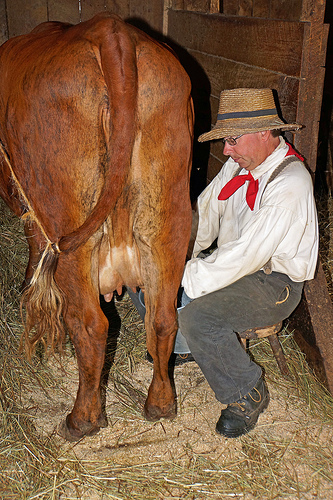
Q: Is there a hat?
A: Yes, there is a hat.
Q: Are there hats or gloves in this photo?
A: Yes, there is a hat.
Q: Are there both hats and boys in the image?
A: No, there is a hat but no boys.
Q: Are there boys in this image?
A: No, there are no boys.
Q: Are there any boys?
A: No, there are no boys.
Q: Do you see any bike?
A: No, there are no bikes.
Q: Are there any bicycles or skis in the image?
A: No, there are no bicycles or skis.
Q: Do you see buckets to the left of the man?
A: Yes, there is a bucket to the left of the man.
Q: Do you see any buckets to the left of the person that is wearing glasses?
A: Yes, there is a bucket to the left of the man.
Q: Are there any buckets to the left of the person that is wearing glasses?
A: Yes, there is a bucket to the left of the man.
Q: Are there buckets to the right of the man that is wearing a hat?
A: No, the bucket is to the left of the man.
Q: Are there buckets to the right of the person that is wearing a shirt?
A: No, the bucket is to the left of the man.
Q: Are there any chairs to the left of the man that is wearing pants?
A: No, there is a bucket to the left of the man.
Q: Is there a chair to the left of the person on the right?
A: No, there is a bucket to the left of the man.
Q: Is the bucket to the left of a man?
A: Yes, the bucket is to the left of a man.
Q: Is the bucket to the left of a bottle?
A: No, the bucket is to the left of a man.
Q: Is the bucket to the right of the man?
A: No, the bucket is to the left of the man.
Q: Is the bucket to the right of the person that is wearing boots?
A: No, the bucket is to the left of the man.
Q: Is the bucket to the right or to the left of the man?
A: The bucket is to the left of the man.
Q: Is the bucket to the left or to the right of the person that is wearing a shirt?
A: The bucket is to the left of the man.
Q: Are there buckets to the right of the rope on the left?
A: Yes, there is a bucket to the right of the rope.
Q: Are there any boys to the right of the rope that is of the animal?
A: No, there is a bucket to the right of the rope.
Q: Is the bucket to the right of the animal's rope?
A: Yes, the bucket is to the right of the rope.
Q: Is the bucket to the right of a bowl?
A: No, the bucket is to the right of the rope.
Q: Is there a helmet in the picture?
A: No, there are no helmets.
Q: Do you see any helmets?
A: No, there are no helmets.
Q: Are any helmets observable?
A: No, there are no helmets.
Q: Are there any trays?
A: No, there are no trays.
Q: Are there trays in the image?
A: No, there are no trays.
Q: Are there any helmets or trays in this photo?
A: No, there are no trays or helmets.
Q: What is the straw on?
A: The straw is on the hay.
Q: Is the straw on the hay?
A: Yes, the straw is on the hay.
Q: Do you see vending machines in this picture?
A: No, there are no vending machines.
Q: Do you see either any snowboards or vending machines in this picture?
A: No, there are no vending machines or snowboards.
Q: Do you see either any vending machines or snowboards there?
A: No, there are no vending machines or snowboards.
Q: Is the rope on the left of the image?
A: Yes, the rope is on the left of the image.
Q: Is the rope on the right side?
A: No, the rope is on the left of the image.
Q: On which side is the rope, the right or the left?
A: The rope is on the left of the image.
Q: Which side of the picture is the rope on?
A: The rope is on the left of the image.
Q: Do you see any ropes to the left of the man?
A: Yes, there is a rope to the left of the man.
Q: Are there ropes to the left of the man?
A: Yes, there is a rope to the left of the man.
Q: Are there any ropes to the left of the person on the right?
A: Yes, there is a rope to the left of the man.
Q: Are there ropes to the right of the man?
A: No, the rope is to the left of the man.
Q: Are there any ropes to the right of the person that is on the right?
A: No, the rope is to the left of the man.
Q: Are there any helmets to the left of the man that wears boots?
A: No, there is a rope to the left of the man.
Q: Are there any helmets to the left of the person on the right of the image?
A: No, there is a rope to the left of the man.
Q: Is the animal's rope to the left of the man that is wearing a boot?
A: Yes, the rope is to the left of the man.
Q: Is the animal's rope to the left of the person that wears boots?
A: Yes, the rope is to the left of the man.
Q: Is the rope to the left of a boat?
A: No, the rope is to the left of the man.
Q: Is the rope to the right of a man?
A: No, the rope is to the left of a man.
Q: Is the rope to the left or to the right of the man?
A: The rope is to the left of the man.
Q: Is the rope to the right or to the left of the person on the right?
A: The rope is to the left of the man.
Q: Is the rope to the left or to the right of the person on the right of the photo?
A: The rope is to the left of the man.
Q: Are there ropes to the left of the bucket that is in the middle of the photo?
A: Yes, there is a rope to the left of the bucket.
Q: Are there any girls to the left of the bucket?
A: No, there is a rope to the left of the bucket.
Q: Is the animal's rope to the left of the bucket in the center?
A: Yes, the rope is to the left of the bucket.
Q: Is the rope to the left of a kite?
A: No, the rope is to the left of the bucket.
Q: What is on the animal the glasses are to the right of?
A: The rope is on the animal.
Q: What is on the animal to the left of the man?
A: The rope is on the animal.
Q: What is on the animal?
A: The rope is on the animal.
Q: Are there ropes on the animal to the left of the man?
A: Yes, there is a rope on the animal.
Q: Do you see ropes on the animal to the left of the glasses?
A: Yes, there is a rope on the animal.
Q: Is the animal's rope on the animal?
A: Yes, the rope is on the animal.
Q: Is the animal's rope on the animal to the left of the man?
A: Yes, the rope is on the animal.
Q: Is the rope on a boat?
A: No, the rope is on the animal.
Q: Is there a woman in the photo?
A: No, there are no women.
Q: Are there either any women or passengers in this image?
A: No, there are no women or passengers.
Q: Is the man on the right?
A: Yes, the man is on the right of the image.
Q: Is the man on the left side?
A: No, the man is on the right of the image.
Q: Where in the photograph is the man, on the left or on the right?
A: The man is on the right of the image.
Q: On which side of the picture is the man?
A: The man is on the right of the image.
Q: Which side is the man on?
A: The man is on the right of the image.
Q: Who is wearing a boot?
A: The man is wearing a boot.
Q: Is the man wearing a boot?
A: Yes, the man is wearing a boot.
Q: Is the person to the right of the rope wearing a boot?
A: Yes, the man is wearing a boot.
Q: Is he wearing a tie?
A: No, the man is wearing a boot.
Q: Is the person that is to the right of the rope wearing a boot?
A: Yes, the man is wearing a boot.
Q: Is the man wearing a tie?
A: No, the man is wearing a boot.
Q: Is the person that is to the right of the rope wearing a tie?
A: No, the man is wearing a boot.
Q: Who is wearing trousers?
A: The man is wearing trousers.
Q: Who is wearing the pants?
A: The man is wearing trousers.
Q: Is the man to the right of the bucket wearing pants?
A: Yes, the man is wearing pants.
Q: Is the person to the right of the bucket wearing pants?
A: Yes, the man is wearing pants.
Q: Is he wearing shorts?
A: No, the man is wearing pants.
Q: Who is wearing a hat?
A: The man is wearing a hat.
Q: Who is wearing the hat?
A: The man is wearing a hat.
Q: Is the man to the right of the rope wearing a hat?
A: Yes, the man is wearing a hat.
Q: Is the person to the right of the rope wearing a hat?
A: Yes, the man is wearing a hat.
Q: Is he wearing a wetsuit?
A: No, the man is wearing a hat.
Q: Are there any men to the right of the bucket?
A: Yes, there is a man to the right of the bucket.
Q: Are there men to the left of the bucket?
A: No, the man is to the right of the bucket.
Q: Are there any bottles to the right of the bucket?
A: No, there is a man to the right of the bucket.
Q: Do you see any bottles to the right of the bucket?
A: No, there is a man to the right of the bucket.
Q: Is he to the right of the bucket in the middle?
A: Yes, the man is to the right of the bucket.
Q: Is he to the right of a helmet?
A: No, the man is to the right of the bucket.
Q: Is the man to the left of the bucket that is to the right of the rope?
A: No, the man is to the right of the bucket.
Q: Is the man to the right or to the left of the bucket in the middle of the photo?
A: The man is to the right of the bucket.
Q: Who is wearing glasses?
A: The man is wearing glasses.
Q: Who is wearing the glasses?
A: The man is wearing glasses.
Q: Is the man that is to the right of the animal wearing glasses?
A: Yes, the man is wearing glasses.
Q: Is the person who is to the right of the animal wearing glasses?
A: Yes, the man is wearing glasses.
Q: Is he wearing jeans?
A: No, the man is wearing glasses.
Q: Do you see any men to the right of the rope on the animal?
A: Yes, there is a man to the right of the rope.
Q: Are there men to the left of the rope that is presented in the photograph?
A: No, the man is to the right of the rope.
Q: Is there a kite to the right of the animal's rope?
A: No, there is a man to the right of the rope.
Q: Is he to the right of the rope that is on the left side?
A: Yes, the man is to the right of the rope.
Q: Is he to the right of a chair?
A: No, the man is to the right of the rope.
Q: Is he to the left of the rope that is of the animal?
A: No, the man is to the right of the rope.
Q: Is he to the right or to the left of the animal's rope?
A: The man is to the right of the rope.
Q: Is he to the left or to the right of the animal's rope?
A: The man is to the right of the rope.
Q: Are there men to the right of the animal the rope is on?
A: Yes, there is a man to the right of the animal.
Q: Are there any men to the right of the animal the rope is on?
A: Yes, there is a man to the right of the animal.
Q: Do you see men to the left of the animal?
A: No, the man is to the right of the animal.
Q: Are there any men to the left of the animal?
A: No, the man is to the right of the animal.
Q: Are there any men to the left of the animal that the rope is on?
A: No, the man is to the right of the animal.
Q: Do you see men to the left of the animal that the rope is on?
A: No, the man is to the right of the animal.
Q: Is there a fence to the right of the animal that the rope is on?
A: No, there is a man to the right of the animal.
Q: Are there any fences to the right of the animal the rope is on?
A: No, there is a man to the right of the animal.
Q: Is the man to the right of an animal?
A: Yes, the man is to the right of an animal.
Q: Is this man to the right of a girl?
A: No, the man is to the right of an animal.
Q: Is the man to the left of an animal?
A: No, the man is to the right of an animal.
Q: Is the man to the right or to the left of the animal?
A: The man is to the right of the animal.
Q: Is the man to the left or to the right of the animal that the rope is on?
A: The man is to the right of the animal.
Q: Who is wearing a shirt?
A: The man is wearing a shirt.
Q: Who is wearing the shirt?
A: The man is wearing a shirt.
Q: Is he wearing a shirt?
A: Yes, the man is wearing a shirt.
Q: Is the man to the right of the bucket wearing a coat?
A: No, the man is wearing a shirt.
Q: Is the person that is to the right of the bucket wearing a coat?
A: No, the man is wearing a shirt.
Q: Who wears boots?
A: The man wears boots.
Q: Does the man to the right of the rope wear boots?
A: Yes, the man wears boots.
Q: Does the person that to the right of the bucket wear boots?
A: Yes, the man wears boots.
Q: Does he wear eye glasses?
A: No, the man wears boots.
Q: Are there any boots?
A: Yes, there are boots.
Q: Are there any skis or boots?
A: Yes, there are boots.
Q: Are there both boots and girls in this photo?
A: No, there are boots but no girls.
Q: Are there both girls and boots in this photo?
A: No, there are boots but no girls.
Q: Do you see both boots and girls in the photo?
A: No, there are boots but no girls.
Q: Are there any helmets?
A: No, there are no helmets.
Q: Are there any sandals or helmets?
A: No, there are no helmets or sandals.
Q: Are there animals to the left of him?
A: Yes, there is an animal to the left of the man.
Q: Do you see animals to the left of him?
A: Yes, there is an animal to the left of the man.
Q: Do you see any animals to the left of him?
A: Yes, there is an animal to the left of the man.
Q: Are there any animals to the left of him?
A: Yes, there is an animal to the left of the man.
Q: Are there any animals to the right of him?
A: No, the animal is to the left of the man.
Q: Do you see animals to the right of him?
A: No, the animal is to the left of the man.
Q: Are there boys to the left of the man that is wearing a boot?
A: No, there is an animal to the left of the man.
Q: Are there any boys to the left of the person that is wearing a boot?
A: No, there is an animal to the left of the man.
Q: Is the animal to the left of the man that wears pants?
A: Yes, the animal is to the left of the man.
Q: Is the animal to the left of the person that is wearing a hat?
A: Yes, the animal is to the left of the man.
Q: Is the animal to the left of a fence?
A: No, the animal is to the left of the man.